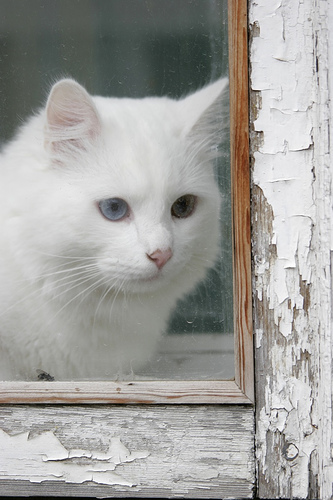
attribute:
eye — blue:
[95, 197, 130, 222]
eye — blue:
[169, 194, 197, 219]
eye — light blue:
[170, 188, 198, 222]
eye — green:
[171, 194, 196, 218]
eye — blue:
[91, 193, 135, 223]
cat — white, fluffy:
[11, 75, 224, 376]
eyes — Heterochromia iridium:
[84, 189, 206, 228]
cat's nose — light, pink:
[146, 245, 176, 269]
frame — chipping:
[245, 0, 332, 499]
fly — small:
[35, 368, 55, 380]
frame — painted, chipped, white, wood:
[1, 0, 253, 408]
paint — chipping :
[246, 0, 329, 498]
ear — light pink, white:
[39, 68, 112, 161]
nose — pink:
[145, 246, 168, 272]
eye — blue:
[97, 193, 130, 222]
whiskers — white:
[13, 247, 135, 330]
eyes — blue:
[90, 190, 202, 224]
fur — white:
[97, 103, 179, 167]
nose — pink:
[149, 248, 172, 268]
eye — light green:
[172, 194, 198, 217]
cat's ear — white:
[44, 77, 100, 166]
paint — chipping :
[6, 404, 325, 496]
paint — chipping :
[227, 0, 331, 497]